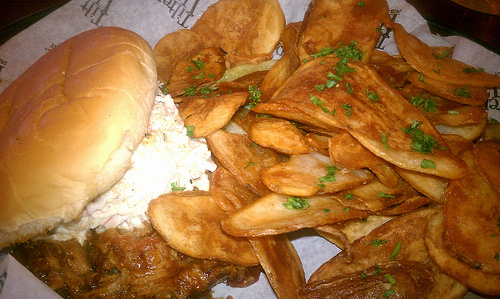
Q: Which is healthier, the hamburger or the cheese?
A: The cheese is healthier than the hamburger.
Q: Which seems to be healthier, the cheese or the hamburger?
A: The cheese is healthier than the hamburger.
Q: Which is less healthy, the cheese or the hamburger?
A: The hamburger is less healthy than the cheese.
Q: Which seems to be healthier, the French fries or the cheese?
A: The cheese is healthier than the French fries.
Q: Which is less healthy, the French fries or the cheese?
A: The French fries is less healthy than the cheese.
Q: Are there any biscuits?
A: No, there are no biscuits.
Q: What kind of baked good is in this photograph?
A: The baked good is a bun.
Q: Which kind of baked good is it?
A: The food is a bun.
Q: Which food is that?
A: This is a bun.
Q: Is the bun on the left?
A: Yes, the bun is on the left of the image.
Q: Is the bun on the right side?
A: No, the bun is on the left of the image.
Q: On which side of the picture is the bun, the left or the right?
A: The bun is on the left of the image.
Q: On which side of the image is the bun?
A: The bun is on the left of the image.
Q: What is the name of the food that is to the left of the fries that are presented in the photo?
A: The food is a bun.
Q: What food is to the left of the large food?
A: The food is a bun.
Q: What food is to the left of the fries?
A: The food is a bun.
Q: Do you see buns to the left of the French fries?
A: Yes, there is a bun to the left of the French fries.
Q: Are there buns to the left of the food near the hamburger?
A: Yes, there is a bun to the left of the French fries.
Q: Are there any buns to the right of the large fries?
A: No, the bun is to the left of the fries.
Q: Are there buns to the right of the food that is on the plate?
A: No, the bun is to the left of the fries.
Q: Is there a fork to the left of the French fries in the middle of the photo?
A: No, there is a bun to the left of the fries.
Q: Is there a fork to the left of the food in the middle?
A: No, there is a bun to the left of the fries.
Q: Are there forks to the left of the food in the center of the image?
A: No, there is a bun to the left of the fries.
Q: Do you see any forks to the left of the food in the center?
A: No, there is a bun to the left of the fries.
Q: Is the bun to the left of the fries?
A: Yes, the bun is to the left of the fries.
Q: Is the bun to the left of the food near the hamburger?
A: Yes, the bun is to the left of the fries.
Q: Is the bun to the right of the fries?
A: No, the bun is to the left of the fries.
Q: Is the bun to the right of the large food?
A: No, the bun is to the left of the fries.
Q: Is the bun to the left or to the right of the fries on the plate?
A: The bun is to the left of the French fries.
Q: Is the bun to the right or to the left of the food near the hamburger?
A: The bun is to the left of the French fries.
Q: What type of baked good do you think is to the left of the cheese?
A: The food is a bun.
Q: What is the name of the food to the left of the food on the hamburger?
A: The food is a bun.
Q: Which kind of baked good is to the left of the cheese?
A: The food is a bun.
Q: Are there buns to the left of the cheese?
A: Yes, there is a bun to the left of the cheese.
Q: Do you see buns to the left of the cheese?
A: Yes, there is a bun to the left of the cheese.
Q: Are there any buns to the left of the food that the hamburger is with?
A: Yes, there is a bun to the left of the cheese.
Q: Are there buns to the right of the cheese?
A: No, the bun is to the left of the cheese.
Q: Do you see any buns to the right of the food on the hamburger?
A: No, the bun is to the left of the cheese.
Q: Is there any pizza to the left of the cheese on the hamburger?
A: No, there is a bun to the left of the cheese.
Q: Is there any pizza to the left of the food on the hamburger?
A: No, there is a bun to the left of the cheese.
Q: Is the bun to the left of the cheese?
A: Yes, the bun is to the left of the cheese.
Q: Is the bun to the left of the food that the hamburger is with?
A: Yes, the bun is to the left of the cheese.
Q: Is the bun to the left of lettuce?
A: No, the bun is to the left of the cheese.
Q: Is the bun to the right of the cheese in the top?
A: No, the bun is to the left of the cheese.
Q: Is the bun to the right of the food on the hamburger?
A: No, the bun is to the left of the cheese.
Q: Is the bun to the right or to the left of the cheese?
A: The bun is to the left of the cheese.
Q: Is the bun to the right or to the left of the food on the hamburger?
A: The bun is to the left of the cheese.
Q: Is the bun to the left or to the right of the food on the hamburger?
A: The bun is to the left of the cheese.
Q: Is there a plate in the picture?
A: Yes, there is a plate.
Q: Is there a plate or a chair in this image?
A: Yes, there is a plate.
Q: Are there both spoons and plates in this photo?
A: No, there is a plate but no spoons.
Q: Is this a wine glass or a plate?
A: This is a plate.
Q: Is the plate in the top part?
A: Yes, the plate is in the top of the image.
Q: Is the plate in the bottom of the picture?
A: No, the plate is in the top of the image.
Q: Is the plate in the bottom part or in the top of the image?
A: The plate is in the top of the image.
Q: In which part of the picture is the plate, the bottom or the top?
A: The plate is in the top of the image.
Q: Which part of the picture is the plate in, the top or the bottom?
A: The plate is in the top of the image.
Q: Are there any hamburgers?
A: Yes, there is a hamburger.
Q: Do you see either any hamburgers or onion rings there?
A: Yes, there is a hamburger.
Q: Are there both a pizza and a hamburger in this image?
A: No, there is a hamburger but no pizzas.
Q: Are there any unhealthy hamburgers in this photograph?
A: Yes, there is an unhealthy hamburger.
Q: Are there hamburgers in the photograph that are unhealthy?
A: Yes, there is a hamburger that is unhealthy.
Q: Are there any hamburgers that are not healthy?
A: Yes, there is a unhealthy hamburger.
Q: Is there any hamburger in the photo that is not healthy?
A: Yes, there is a unhealthy hamburger.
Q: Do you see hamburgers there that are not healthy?
A: Yes, there is a unhealthy hamburger.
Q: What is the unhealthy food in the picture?
A: The food is a hamburger.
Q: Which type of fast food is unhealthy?
A: The fast food is a hamburger.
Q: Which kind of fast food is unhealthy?
A: The fast food is a hamburger.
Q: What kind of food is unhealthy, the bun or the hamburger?
A: The hamburger is unhealthy.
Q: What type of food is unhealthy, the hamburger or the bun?
A: The hamburger is unhealthy.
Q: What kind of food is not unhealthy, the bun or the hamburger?
A: The bun is not unhealthy.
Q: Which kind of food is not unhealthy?
A: The food is a bun.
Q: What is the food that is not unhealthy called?
A: The food is a bun.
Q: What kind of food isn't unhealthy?
A: The food is a bun.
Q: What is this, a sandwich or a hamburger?
A: This is a hamburger.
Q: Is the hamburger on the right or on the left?
A: The hamburger is on the left of the image.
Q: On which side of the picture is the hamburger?
A: The hamburger is on the left of the image.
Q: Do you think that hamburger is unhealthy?
A: Yes, the hamburger is unhealthy.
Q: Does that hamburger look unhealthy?
A: Yes, the hamburger is unhealthy.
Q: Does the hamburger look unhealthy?
A: Yes, the hamburger is unhealthy.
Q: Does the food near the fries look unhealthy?
A: Yes, the hamburger is unhealthy.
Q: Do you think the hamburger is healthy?
A: No, the hamburger is unhealthy.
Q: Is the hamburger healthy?
A: No, the hamburger is unhealthy.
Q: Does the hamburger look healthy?
A: No, the hamburger is unhealthy.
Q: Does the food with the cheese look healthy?
A: No, the hamburger is unhealthy.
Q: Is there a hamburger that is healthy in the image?
A: No, there is a hamburger but it is unhealthy.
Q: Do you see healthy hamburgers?
A: No, there is a hamburger but it is unhealthy.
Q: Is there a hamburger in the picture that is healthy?
A: No, there is a hamburger but it is unhealthy.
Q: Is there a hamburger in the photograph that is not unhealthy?
A: No, there is a hamburger but it is unhealthy.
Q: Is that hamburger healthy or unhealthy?
A: The hamburger is unhealthy.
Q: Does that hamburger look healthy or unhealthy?
A: The hamburger is unhealthy.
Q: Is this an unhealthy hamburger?
A: Yes, this is an unhealthy hamburger.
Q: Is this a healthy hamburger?
A: No, this is an unhealthy hamburger.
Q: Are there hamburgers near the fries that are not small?
A: Yes, there is a hamburger near the fries.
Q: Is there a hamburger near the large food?
A: Yes, there is a hamburger near the fries.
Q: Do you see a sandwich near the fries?
A: No, there is a hamburger near the fries.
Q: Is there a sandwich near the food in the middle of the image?
A: No, there is a hamburger near the fries.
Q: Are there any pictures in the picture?
A: No, there are no pictures.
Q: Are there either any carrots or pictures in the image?
A: No, there are no pictures or carrots.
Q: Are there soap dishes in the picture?
A: No, there are no soap dishes.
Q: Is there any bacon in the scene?
A: Yes, there is bacon.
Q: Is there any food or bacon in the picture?
A: Yes, there is bacon.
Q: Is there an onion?
A: No, there are no onions.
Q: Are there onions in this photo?
A: No, there are no onions.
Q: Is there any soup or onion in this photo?
A: No, there are no onions or soup.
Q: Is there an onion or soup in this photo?
A: No, there are no onions or soup.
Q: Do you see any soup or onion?
A: No, there are no onions or soup.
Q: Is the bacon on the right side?
A: Yes, the bacon is on the right of the image.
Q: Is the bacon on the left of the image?
A: No, the bacon is on the right of the image.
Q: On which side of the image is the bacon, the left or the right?
A: The bacon is on the right of the image.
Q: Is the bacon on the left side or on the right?
A: The bacon is on the right of the image.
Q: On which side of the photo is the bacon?
A: The bacon is on the right of the image.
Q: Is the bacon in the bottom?
A: Yes, the bacon is in the bottom of the image.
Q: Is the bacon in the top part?
A: No, the bacon is in the bottom of the image.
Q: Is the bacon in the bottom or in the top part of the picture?
A: The bacon is in the bottom of the image.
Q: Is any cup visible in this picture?
A: No, there are no cups.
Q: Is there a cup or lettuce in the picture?
A: No, there are no cups or lettuce.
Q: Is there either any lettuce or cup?
A: No, there are no cups or lettuce.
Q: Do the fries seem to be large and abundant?
A: Yes, the fries are large and abundant.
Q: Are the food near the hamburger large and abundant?
A: Yes, the fries are large and abundant.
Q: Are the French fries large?
A: Yes, the French fries are large.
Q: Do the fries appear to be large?
A: Yes, the fries are large.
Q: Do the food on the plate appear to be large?
A: Yes, the fries are large.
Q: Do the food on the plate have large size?
A: Yes, the fries are large.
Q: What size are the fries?
A: The fries are large.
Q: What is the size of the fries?
A: The fries are large.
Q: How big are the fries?
A: The fries are large.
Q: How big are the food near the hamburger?
A: The fries are large.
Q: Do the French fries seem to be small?
A: No, the French fries are large.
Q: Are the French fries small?
A: No, the French fries are large.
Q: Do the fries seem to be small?
A: No, the fries are large.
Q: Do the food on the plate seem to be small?
A: No, the fries are large.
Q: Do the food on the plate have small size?
A: No, the fries are large.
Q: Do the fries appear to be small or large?
A: The fries are large.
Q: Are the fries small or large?
A: The fries are large.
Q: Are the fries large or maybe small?
A: The fries are large.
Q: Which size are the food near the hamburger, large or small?
A: The fries are large.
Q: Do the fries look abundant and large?
A: Yes, the fries are abundant and large.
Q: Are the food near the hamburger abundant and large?
A: Yes, the fries are abundant and large.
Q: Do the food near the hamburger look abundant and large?
A: Yes, the fries are abundant and large.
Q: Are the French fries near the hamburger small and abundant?
A: No, the French fries are abundant but large.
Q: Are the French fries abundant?
A: Yes, the French fries are abundant.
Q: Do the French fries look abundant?
A: Yes, the French fries are abundant.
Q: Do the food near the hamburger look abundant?
A: Yes, the French fries are abundant.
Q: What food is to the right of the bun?
A: The food is fries.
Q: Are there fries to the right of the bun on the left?
A: Yes, there are fries to the right of the bun.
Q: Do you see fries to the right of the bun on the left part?
A: Yes, there are fries to the right of the bun.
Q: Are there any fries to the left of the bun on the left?
A: No, the fries are to the right of the bun.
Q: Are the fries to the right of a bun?
A: Yes, the fries are to the right of a bun.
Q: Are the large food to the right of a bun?
A: Yes, the fries are to the right of a bun.